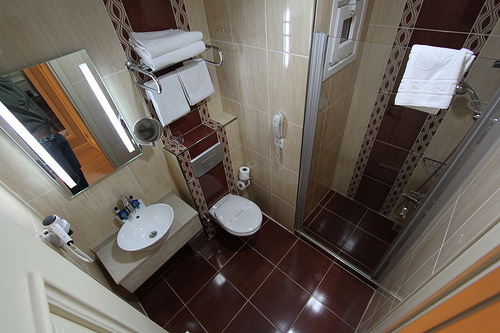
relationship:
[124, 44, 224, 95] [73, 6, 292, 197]
shelf mounted to wall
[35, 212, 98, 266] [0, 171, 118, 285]
dryer attached to wall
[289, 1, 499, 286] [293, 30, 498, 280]
shower with door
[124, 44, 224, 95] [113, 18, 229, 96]
shelf folded on shelf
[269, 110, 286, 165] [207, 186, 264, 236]
telephone next to toilet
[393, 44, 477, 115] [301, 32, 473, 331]
towel hanging over glass